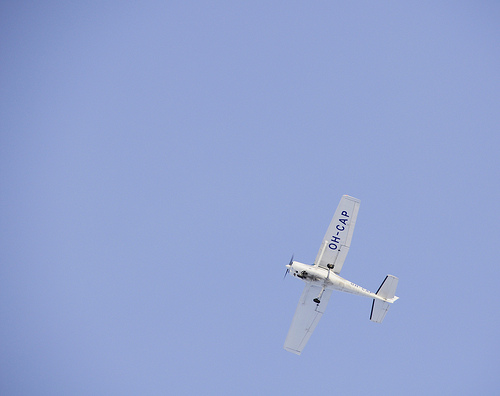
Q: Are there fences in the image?
A: No, there are no fences.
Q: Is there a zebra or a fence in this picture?
A: No, there are no fences or zebras.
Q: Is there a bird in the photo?
A: No, there are no birds.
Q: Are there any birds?
A: No, there are no birds.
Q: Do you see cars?
A: No, there are no cars.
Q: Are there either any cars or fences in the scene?
A: No, there are no cars or fences.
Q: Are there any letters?
A: Yes, there are letters.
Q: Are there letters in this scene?
A: Yes, there are letters.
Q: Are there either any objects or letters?
A: Yes, there are letters.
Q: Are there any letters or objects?
A: Yes, there are letters.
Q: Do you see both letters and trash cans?
A: No, there are letters but no trash cans.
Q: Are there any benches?
A: No, there are no benches.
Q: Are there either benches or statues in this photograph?
A: No, there are no benches or statues.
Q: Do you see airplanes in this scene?
A: Yes, there is an airplane.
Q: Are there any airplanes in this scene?
A: Yes, there is an airplane.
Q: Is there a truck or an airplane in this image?
A: Yes, there is an airplane.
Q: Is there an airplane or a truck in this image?
A: Yes, there is an airplane.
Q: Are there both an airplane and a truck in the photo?
A: No, there is an airplane but no trucks.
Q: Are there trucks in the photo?
A: No, there are no trucks.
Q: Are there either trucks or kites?
A: No, there are no trucks or kites.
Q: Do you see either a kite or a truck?
A: No, there are no trucks or kites.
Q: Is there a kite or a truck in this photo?
A: No, there are no trucks or kites.